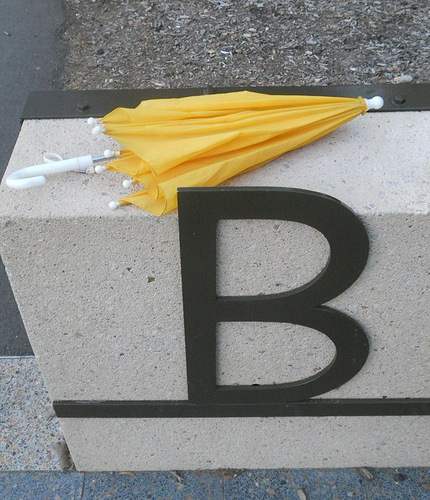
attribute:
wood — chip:
[169, 468, 197, 482]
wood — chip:
[305, 28, 427, 87]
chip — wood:
[370, 64, 388, 76]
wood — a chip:
[114, 471, 137, 477]